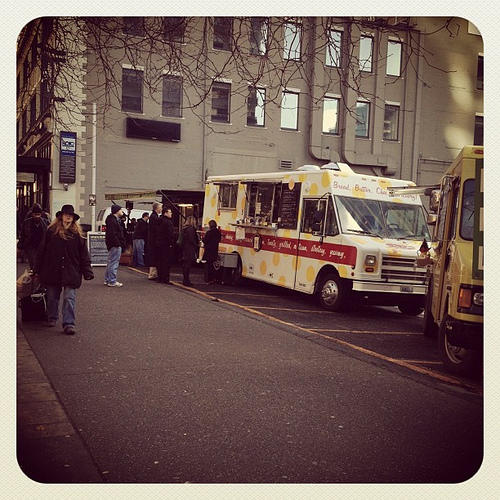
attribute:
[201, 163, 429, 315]
truck — vehicle, white, food-selling van, food truck, yellow, polka-dotted van, food vendor van, a van, on the ground, white with spots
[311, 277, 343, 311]
front wheel — on a vehicle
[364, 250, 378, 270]
front headlight — on a vehicle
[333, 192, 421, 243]
front windshield — on a vehicle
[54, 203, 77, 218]
black hat — on a head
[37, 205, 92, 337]
walking person — woman in black hat, wearing black hat, pulling luggage, walking on concrete, a woman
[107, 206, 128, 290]
man — wearing blue jeans, standing, in line, person, wearing beanie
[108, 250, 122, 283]
pants — blue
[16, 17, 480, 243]
building — behind the van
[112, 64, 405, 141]
windows — on building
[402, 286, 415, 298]
license plate — on front of vehicle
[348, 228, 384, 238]
windshield wiper — on vehicle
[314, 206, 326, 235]
side view mirror — on a vehicle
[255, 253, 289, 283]
polka dots — yellow spots, decorating van, truck design, yellow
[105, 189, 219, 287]
crowd of people — waiting for food, a line for food van, part of scene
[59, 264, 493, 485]
road — asphalt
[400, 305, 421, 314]
tire — on van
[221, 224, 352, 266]
stripe — red, painted on truck, painted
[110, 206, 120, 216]
beanie — black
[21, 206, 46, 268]
woman — walking on concrete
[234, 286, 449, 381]
lines — yellow, painted on asphalt, parking lines, painted, painted on concrete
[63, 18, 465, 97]
tree branches — hanging low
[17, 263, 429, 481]
walkway — black asphalt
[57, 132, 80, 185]
sign — blue white, black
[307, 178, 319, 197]
dot — polka dot